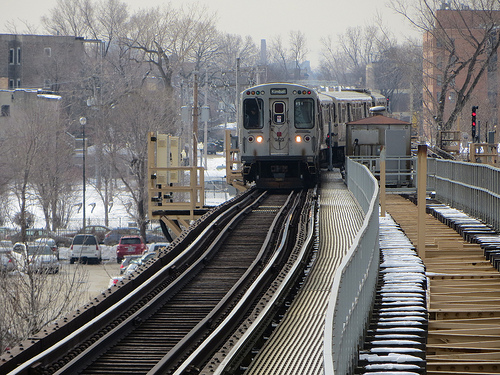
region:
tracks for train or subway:
[40, 167, 397, 368]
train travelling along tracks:
[237, 37, 392, 199]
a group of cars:
[3, 230, 157, 275]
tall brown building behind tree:
[405, 4, 496, 162]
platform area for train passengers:
[318, 120, 497, 368]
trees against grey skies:
[50, 4, 281, 69]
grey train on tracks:
[237, 40, 390, 192]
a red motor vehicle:
[109, 230, 154, 268]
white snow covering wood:
[366, 203, 466, 371]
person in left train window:
[235, 78, 330, 193]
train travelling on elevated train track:
[236, 58, 391, 228]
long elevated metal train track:
[1, 191, 250, 374]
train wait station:
[337, 106, 425, 194]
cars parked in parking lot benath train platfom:
[4, 222, 173, 299]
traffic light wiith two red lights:
[465, 99, 488, 156]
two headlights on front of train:
[249, 133, 317, 150]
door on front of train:
[266, 96, 291, 156]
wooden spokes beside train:
[376, 183, 497, 368]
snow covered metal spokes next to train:
[363, 248, 424, 373]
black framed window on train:
[288, 96, 318, 133]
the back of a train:
[239, 82, 319, 162]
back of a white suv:
[70, 232, 100, 261]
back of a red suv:
[116, 235, 145, 257]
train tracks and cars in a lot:
[0, 187, 326, 371]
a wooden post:
[414, 146, 431, 261]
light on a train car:
[293, 134, 302, 143]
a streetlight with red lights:
[468, 105, 478, 137]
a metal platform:
[146, 134, 236, 216]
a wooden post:
[380, 162, 385, 216]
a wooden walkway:
[425, 257, 495, 370]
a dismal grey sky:
[0, 1, 496, 67]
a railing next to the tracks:
[321, 156, 383, 368]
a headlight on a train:
[293, 134, 301, 146]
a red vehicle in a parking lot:
[111, 232, 146, 260]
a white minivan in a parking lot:
[9, 238, 58, 272]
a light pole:
[72, 111, 98, 231]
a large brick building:
[0, 28, 114, 190]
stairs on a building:
[59, 123, 93, 164]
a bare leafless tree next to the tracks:
[408, 5, 497, 151]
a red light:
[467, 107, 479, 128]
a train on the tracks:
[201, 70, 368, 202]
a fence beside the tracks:
[340, 150, 381, 371]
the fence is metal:
[318, 156, 382, 373]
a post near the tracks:
[413, 147, 431, 262]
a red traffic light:
[468, 102, 485, 147]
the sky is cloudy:
[245, 5, 333, 38]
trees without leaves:
[2, 108, 84, 219]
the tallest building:
[420, 7, 499, 146]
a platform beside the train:
[133, 125, 240, 226]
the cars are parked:
[3, 232, 148, 272]